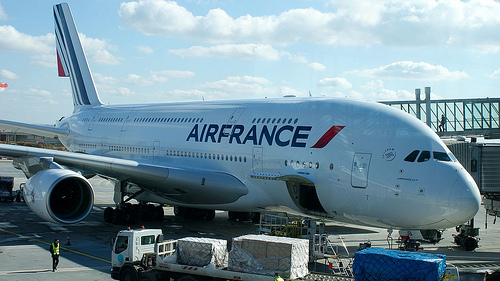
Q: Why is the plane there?
A: It is getting ready for a flight.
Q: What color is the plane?
A: White.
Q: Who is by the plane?
A: A man.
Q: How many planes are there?
A: One.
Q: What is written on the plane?
A: AirFrance.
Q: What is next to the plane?
A: A truck.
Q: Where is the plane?
A: On the runway.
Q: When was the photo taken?
A: During the day.